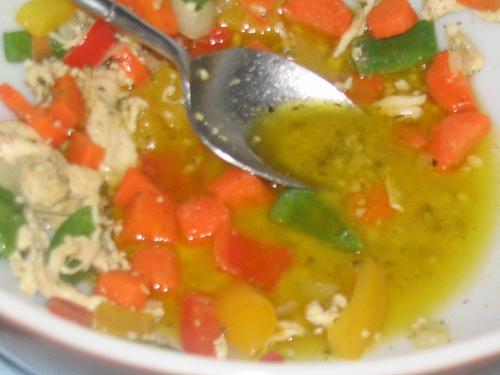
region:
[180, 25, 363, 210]
A spoon in the soup.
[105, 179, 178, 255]
Carrots in the bowl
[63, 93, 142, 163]
Chicken pieces in the soup.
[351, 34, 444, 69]
Green peppers in the soup.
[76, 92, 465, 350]
Food in the bowl.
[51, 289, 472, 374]
The bowl is white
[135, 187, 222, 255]
The carrots are orange.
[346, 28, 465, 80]
A green vegetable in the bowl.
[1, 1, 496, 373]
a soup is on a dish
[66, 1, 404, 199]
the spoon is in the soup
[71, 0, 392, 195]
the spoon is made of metal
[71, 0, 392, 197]
the spoon is shiny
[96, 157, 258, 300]
slices of carrots are in the soup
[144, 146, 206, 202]
slices of tomato are in the soup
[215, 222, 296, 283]
slices of tomato are in the soup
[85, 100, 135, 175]
chicken meat is on the soup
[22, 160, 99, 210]
chicken meat is on the soup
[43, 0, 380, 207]
this is a spoon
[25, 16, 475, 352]
this is some soup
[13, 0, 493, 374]
this is a bowl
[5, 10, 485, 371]
the bowl is white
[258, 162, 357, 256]
this is a green veggie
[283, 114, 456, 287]
this is yellow soup broth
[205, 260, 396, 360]
this is a yellow veggie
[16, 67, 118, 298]
white meat in soup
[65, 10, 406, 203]
Spoon in bowl of vegetable soup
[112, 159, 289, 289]
Orange carrots in soup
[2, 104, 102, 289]
Chicken in vegetable soup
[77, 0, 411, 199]
Spoon made of stainless steel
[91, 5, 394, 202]
Spoon is a silver color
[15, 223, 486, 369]
White glass bowl with soup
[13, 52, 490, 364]
Vegetables in a bowl of soup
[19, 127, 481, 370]
Vegetables and chicken in a bowl of soup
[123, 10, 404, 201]
Spoon scooping up soup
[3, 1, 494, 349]
a bowl of food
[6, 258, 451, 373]
a white bowl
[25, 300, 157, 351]
the edge of the bowl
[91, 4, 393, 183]
spoon in the bowl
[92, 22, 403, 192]
a spoon with soup on it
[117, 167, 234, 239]
carrots in the soup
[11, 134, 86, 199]
meat in the soup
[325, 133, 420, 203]
broth of the soup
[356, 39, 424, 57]
green peppers in the soup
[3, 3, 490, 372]
a bowl of soup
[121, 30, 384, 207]
silver spoon in the bowl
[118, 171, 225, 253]
carrots in the bowl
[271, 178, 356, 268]
green pepper in the bowl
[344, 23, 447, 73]
green pepper in the bowl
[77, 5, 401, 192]
silver spoon in the bowl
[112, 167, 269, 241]
carrot in the bowl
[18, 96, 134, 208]
chicken in the bowl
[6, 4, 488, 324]
chicken soup in the bowl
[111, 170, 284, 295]
carrots in the bowl of the soup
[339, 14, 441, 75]
celery in the bowl of soup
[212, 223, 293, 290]
tomato in the bowl of soup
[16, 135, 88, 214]
chicken in the bowl of soup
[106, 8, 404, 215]
soup in the bowl of soup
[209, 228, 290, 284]
cut carrot in soup